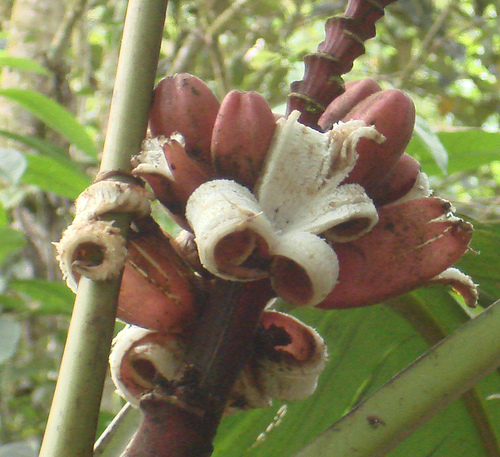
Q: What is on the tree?
A: Bad bananas.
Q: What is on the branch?
A: The bad bananas.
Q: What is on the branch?
A: The open bananas.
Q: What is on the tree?
A: The open bananas.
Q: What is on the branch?
A: The red open bananas.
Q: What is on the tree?
A: The red open bananas.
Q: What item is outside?
A: The bananas.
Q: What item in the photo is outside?
A: The red bananas.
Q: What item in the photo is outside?
A: The open bananas.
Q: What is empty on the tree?
A: Peel of banana.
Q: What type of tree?
A: Banana.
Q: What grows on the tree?
A: Bananasa.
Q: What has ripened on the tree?
A: Bananas.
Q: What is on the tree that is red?
A: Banana stalk.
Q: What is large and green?
A: Banana Leaves.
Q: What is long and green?
A: Banana stalk.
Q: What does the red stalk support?
A: Banana.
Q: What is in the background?
A: Trees.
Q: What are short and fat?
A: Red bananas.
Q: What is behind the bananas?
A: Leaves.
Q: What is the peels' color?
A: Purple.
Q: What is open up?
A: A peel.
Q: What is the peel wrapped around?
A: Stick.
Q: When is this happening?
A: During the day time.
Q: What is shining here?
A: Sun.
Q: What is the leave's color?
A: Green.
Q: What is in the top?
A: Trees.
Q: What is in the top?
A: Fruits.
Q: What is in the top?
A: Food.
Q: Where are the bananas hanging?
A: Top.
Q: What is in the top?
A: Stem.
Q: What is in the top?
A: Leaves.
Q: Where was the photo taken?
A: In the woods.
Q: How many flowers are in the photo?
A: One.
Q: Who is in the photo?
A: No one.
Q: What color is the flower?
A: Red.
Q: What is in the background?
A: Leaves and shrubs.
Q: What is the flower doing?
A: Curling.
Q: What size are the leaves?
A: Large.